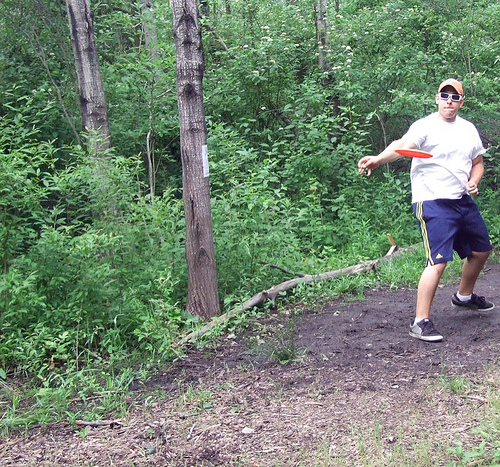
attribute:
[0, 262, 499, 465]
trail — muddy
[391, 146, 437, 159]
frisbee — red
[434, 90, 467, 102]
glasses — white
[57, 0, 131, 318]
tree — green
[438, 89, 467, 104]
glasses — for sun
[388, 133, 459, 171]
frisbee — orange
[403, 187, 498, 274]
shorts — blue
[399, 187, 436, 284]
stripes — yellow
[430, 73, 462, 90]
hat — orange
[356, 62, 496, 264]
shorts — blue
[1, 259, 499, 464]
dirt — dark brown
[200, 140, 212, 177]
sign — white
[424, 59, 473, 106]
hat — orange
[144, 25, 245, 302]
trunk — long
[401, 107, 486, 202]
tshirt — white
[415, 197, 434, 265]
stripes — yellow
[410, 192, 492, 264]
shorts — blue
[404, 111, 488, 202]
shirt — white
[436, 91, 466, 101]
sunglasses — white, rimmed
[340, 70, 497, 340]
man — standing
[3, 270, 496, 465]
ground — brown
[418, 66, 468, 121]
sunglasses — dark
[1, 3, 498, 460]
foliage — green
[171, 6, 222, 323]
trunk — brown